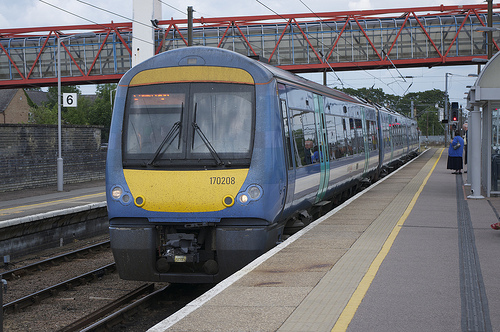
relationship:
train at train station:
[117, 50, 398, 183] [476, 52, 500, 193]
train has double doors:
[117, 50, 398, 183] [308, 99, 341, 188]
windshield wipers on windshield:
[175, 105, 202, 161] [131, 89, 247, 172]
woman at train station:
[439, 120, 471, 174] [476, 52, 500, 193]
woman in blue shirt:
[439, 120, 471, 174] [449, 138, 467, 155]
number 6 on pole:
[63, 86, 74, 100] [53, 30, 75, 191]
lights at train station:
[42, 30, 112, 61] [476, 52, 500, 193]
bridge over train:
[232, 8, 476, 91] [117, 50, 398, 183]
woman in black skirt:
[439, 120, 471, 174] [446, 157, 462, 168]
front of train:
[117, 58, 277, 190] [117, 50, 398, 183]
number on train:
[203, 172, 247, 189] [117, 50, 398, 183]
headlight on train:
[231, 179, 270, 207] [117, 50, 398, 183]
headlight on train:
[104, 181, 127, 207] [117, 50, 398, 183]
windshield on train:
[131, 89, 247, 172] [117, 50, 398, 183]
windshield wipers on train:
[175, 105, 202, 161] [117, 50, 398, 183]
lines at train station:
[371, 163, 451, 186] [476, 52, 500, 193]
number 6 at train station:
[63, 86, 74, 100] [476, 52, 500, 193]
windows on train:
[282, 104, 324, 161] [117, 50, 398, 183]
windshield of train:
[131, 89, 247, 172] [117, 50, 398, 183]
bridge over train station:
[232, 8, 476, 91] [476, 52, 500, 193]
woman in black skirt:
[439, 120, 471, 174] [446, 162, 460, 176]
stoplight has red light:
[437, 86, 463, 122] [437, 115, 462, 119]